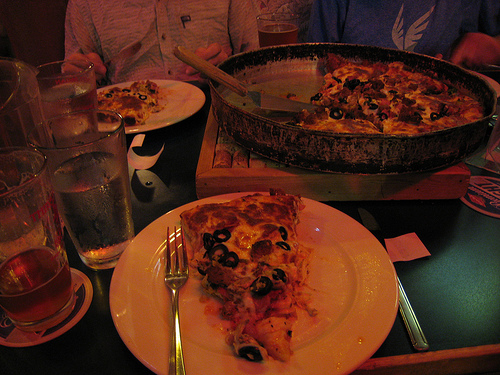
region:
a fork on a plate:
[162, 224, 190, 374]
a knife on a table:
[352, 204, 427, 350]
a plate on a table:
[102, 192, 405, 374]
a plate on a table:
[65, 78, 208, 134]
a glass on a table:
[25, 108, 141, 268]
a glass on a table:
[26, 53, 96, 198]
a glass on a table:
[0, 143, 75, 333]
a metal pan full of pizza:
[205, 41, 499, 177]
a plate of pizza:
[106, 190, 398, 371]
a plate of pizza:
[70, 79, 208, 137]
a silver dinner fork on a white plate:
[164, 221, 189, 373]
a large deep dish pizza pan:
[206, 38, 496, 173]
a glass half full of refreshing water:
[32, 105, 137, 272]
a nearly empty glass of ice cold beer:
[0, 149, 77, 331]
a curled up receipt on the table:
[127, 133, 165, 173]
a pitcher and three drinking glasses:
[2, 56, 132, 331]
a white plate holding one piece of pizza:
[104, 187, 397, 374]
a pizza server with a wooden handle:
[172, 40, 336, 117]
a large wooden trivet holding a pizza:
[192, 80, 471, 200]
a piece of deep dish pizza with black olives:
[182, 189, 302, 364]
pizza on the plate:
[120, 168, 366, 357]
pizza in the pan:
[233, 38, 467, 145]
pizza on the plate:
[89, 78, 193, 128]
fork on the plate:
[139, 245, 199, 369]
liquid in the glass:
[3, 223, 101, 331]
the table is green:
[431, 218, 476, 323]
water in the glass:
[52, 122, 125, 246]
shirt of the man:
[118, 21, 197, 76]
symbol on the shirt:
[358, 0, 443, 60]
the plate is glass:
[315, 210, 387, 326]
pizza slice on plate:
[179, 213, 299, 350]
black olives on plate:
[201, 225, 293, 342]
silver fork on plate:
[127, 225, 198, 369]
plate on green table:
[90, 225, 339, 367]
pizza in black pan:
[202, 53, 485, 163]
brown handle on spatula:
[155, 44, 320, 124]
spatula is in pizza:
[185, 60, 331, 138]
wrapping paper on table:
[122, 138, 169, 163]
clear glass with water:
[36, 114, 129, 278]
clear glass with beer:
[4, 158, 79, 311]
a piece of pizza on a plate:
[175, 180, 314, 367]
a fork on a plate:
[160, 224, 195, 374]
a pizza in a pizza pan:
[189, 33, 499, 169]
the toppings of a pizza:
[224, 227, 278, 292]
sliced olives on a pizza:
[204, 225, 239, 267]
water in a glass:
[38, 114, 138, 283]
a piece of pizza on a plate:
[94, 67, 195, 127]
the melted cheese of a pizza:
[232, 229, 269, 256]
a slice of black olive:
[234, 341, 266, 366]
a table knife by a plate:
[350, 199, 435, 359]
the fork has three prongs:
[165, 222, 190, 374]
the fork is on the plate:
[109, 190, 398, 374]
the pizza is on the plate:
[111, 188, 398, 373]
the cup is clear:
[28, 106, 135, 271]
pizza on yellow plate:
[170, 178, 312, 365]